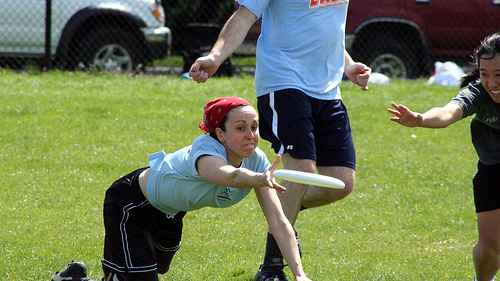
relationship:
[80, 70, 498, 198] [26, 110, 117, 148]
people playing on green grass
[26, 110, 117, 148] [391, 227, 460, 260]
green grass on ground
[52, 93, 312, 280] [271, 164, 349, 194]
girl throwing frisbee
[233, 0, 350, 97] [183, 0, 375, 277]
shirt on player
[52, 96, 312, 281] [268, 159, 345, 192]
girl reaching frisbee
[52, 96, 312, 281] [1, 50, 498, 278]
girl on ground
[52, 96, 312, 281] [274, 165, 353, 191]
girl reaching frisbee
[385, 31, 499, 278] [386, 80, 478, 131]
woman with arm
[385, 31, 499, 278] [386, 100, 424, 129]
woman with hand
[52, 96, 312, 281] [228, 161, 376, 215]
girl diving for frisbee